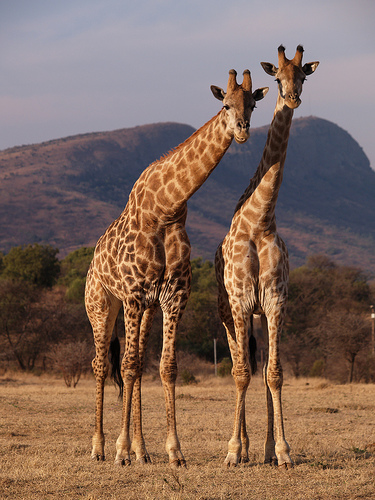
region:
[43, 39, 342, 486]
these are two giraffes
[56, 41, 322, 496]
the giraffes are tall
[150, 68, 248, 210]
the giraffe has long neck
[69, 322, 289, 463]
the giraffes have long legs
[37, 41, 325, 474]
the giraffes are brown and white in color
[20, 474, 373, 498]
the grass are dry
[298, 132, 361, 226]
this is a hill behind the giraffes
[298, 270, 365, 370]
the giraffes are beside the hill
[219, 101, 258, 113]
the eyes are wide open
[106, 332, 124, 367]
the tail is black in color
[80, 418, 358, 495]
eight hooves standing in grass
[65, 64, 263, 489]
giraffe leaning to the right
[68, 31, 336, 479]
two giraffes standing side by side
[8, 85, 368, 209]
mountains in the background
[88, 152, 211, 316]
brown spots on a giraffe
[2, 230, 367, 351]
row of trees behind giraffes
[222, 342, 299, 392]
knee joint of a giraffe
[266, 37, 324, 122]
head of a giraffe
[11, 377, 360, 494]
dry brown grass on the plains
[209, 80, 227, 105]
ear of a giraffe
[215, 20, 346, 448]
Large spotted brown giraffe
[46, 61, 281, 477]
Large spotted brown giraffe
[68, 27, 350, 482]
Group of two giraffes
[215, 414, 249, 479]
Large brown giraffe hoof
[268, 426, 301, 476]
Large brown giraffe hoof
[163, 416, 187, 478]
Large brown giraffe hoof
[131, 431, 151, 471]
Large brown giraffe hoof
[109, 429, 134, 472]
Large brown giraffe hoof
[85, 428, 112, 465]
Large brown giraffe hoof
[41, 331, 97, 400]
Small brown shrub with no leaves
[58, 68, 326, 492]
two giraffe standing side by side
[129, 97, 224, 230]
long neck with brown yellow spots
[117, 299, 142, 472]
long front leg of giraffe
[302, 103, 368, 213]
outline of hills in the distance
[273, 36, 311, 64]
horns on top giraffes head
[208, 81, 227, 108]
pointed ear of giraffe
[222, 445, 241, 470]
grey brown hoove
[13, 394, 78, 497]
brown dry grass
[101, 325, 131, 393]
tail between the legs of giraffe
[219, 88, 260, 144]
face of giraffe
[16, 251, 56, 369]
there are some trees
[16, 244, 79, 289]
the tree leaves are green in color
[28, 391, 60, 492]
this is dry grass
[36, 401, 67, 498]
the grass is brown in color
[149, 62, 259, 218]
the giraffe's neck is bent to the left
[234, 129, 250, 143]
the giraffe's mouth is open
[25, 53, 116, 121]
this is the sky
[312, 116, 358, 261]
this is a tall mountain